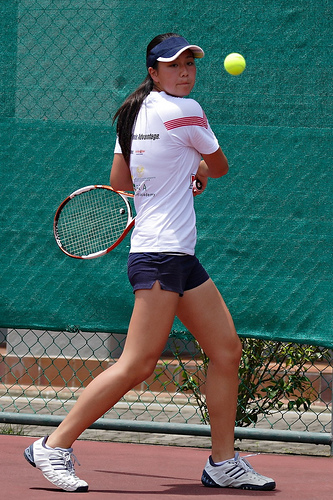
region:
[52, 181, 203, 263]
red and white tennis racket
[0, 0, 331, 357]
green cover over fence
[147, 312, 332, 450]
green leafy plant next to fence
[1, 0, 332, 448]
silver metal chain-link fence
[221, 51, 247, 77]
small globular yellow tennis ball in the air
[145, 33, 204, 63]
blue and white visor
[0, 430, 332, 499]
red hard court tennis court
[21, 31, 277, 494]
female tennis player swinging at tennis ball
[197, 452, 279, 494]
white black and gray tennis shoe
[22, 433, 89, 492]
white black and gray tennis shoe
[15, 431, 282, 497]
Girl wearing shoes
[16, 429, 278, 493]
Girl is wearing shoes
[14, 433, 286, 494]
Girl is wearing white and dark blue shoes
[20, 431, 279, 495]
Girl wearing white and dark blue shoes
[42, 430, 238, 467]
Girl wearing socks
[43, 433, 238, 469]
Girl is wearing socks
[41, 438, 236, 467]
Girl wearing white socks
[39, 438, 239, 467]
Girl is wearing white socks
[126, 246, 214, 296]
Girl wearing dark blue shorts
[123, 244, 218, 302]
Girl is wearing dark blue shorts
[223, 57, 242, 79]
TENNIS BALL IN THE AIR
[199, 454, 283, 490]
WOMAN WEARING TENNIS SHOES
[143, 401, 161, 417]
FENCE BEHIND THE WOMAN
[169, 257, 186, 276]
LADY HAS ON BLUE SHORTS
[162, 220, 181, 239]
WOMAN WEARING A WHITE TEE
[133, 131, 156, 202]
WORDS ON THE BACK OF SHIRT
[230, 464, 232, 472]
STRIPES OF BLUE ON SIDE OF SHOE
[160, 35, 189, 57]
SUNVISOR ON THE WOMAN HEAD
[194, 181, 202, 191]
TENNIS RACKET IN WOMAN HAND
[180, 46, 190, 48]
WHITE TRIMMED AROUND SUNVISOR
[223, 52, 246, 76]
a yellow tennis ball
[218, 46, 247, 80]
a tennis ball in the air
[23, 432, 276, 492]
a pair of white and blue athletic shoes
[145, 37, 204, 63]
a blue and white sun visor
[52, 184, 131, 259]
a black, red and white tennis racket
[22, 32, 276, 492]
an amateur female tennis player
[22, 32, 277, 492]
a tennis player preparing to hit the ball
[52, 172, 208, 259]
a tennis racket in the woman's hands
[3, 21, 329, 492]
a amateur female tennis player on the court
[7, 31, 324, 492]
a woman playing tennis on the court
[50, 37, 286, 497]
a woman playing some tennis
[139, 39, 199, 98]
the head of a woman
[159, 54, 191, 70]
the eyes of a woman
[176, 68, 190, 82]
the nose of a woman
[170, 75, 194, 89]
the mouth of a woman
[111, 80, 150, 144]
the hair of a woman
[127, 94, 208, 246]
the white shirt of a woman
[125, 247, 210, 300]
the shorts of a woman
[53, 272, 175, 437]
the right leg of a woman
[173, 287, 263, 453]
the left leg of a woman